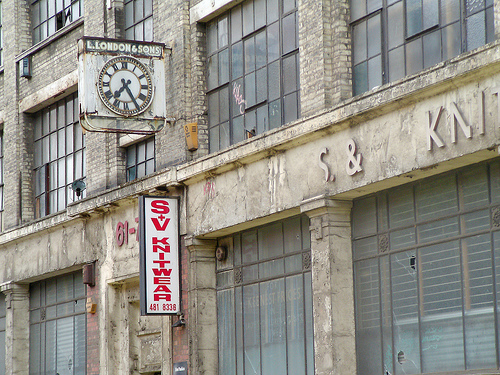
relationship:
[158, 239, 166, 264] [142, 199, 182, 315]
letters on sign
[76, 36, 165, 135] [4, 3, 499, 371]
clock on building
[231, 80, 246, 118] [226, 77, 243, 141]
letters on window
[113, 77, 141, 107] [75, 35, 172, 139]
hands on clock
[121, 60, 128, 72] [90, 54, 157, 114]
roman numberals on clock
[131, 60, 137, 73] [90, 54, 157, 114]
roman numberals on clock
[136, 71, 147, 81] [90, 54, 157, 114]
roman numberals on clock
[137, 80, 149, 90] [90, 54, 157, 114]
roman numberals on clock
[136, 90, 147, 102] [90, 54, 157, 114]
roman numberals on clock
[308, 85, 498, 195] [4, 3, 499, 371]
letters on side of building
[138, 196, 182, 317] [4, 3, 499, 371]
sign on side of building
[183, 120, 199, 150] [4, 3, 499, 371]
container on side of building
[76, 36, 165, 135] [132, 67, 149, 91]
clock with roman numerals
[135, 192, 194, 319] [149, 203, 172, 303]
sign with lettering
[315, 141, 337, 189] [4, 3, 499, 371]
s on building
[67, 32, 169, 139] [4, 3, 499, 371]
clock attached to building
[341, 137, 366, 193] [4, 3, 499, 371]
& sign on building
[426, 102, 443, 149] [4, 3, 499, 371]
k on building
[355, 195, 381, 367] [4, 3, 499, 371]
window on building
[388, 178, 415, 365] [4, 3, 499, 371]
window on building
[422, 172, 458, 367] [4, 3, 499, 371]
window on building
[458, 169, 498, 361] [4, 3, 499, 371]
window on building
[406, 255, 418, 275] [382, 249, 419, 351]
hole in window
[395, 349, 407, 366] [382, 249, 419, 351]
hole in window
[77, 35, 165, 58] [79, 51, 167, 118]
rusty sign on clock